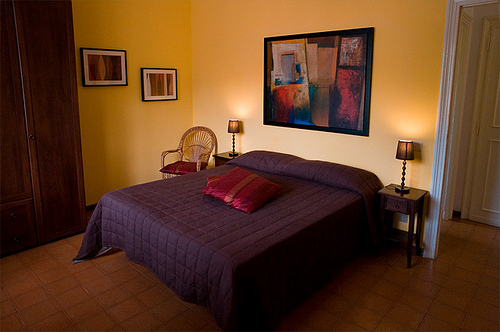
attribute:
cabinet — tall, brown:
[0, 3, 90, 260]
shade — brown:
[225, 118, 241, 133]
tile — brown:
[326, 279, 391, 329]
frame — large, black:
[262, 27, 374, 135]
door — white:
[467, 18, 498, 228]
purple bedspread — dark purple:
[115, 142, 276, 233]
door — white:
[453, 1, 498, 228]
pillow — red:
[198, 163, 285, 214]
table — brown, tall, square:
[381, 182, 428, 257]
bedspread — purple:
[71, 150, 383, 330]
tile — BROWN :
[43, 274, 84, 312]